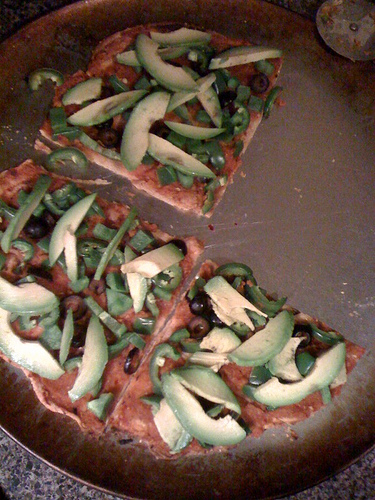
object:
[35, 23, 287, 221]
pizza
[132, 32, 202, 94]
avocado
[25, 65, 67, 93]
jalapenos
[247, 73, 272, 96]
black olive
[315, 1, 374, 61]
pizza cutter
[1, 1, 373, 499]
pizza pan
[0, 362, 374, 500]
burnt edge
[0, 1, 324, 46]
table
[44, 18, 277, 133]
crust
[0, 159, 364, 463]
pizza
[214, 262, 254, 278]
pepper